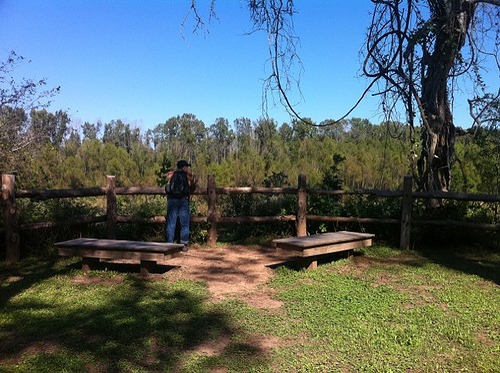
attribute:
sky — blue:
[278, 4, 332, 68]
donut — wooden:
[284, 170, 435, 237]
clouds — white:
[174, 48, 226, 107]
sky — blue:
[2, 2, 499, 132]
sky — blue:
[110, 35, 202, 90]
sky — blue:
[92, 24, 235, 91]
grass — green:
[307, 270, 364, 330]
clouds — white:
[185, 35, 235, 63]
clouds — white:
[73, 95, 123, 110]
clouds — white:
[134, 102, 151, 120]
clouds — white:
[82, 85, 97, 95]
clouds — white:
[35, 58, 45, 66]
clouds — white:
[318, 87, 338, 104]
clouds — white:
[1, 90, 198, 145]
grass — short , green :
[292, 269, 418, 338]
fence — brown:
[4, 172, 498, 251]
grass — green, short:
[0, 235, 499, 371]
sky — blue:
[0, 1, 499, 146]